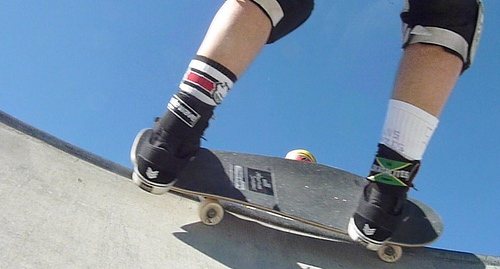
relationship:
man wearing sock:
[124, 0, 484, 247] [379, 98, 439, 163]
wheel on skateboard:
[186, 203, 248, 235] [179, 141, 447, 243]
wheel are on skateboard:
[375, 243, 401, 262] [229, 171, 356, 204]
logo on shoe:
[357, 221, 380, 243] [344, 165, 413, 255]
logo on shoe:
[138, 162, 160, 179] [134, 115, 192, 197]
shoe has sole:
[126, 125, 178, 195] [131, 127, 171, 194]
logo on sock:
[211, 80, 232, 102] [180, 53, 235, 112]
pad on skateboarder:
[394, 0, 485, 68] [130, 3, 487, 248]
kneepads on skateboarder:
[225, 0, 317, 45] [130, 3, 487, 248]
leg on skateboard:
[388, 10, 461, 217] [136, 138, 449, 255]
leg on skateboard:
[163, 3, 290, 144] [136, 138, 449, 255]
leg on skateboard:
[363, 0, 485, 207] [136, 138, 449, 255]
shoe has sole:
[341, 198, 446, 252] [131, 127, 179, 194]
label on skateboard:
[182, 160, 272, 197] [128, 130, 442, 267]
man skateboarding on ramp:
[124, 0, 484, 247] [1, 114, 494, 267]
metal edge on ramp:
[61, 133, 101, 178] [1, 114, 500, 269]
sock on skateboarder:
[166, 54, 236, 136] [130, 3, 487, 248]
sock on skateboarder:
[379, 98, 439, 163] [130, 3, 487, 248]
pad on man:
[400, 0, 484, 75] [124, 0, 484, 247]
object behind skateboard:
[284, 146, 316, 163] [166, 145, 444, 263]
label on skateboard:
[229, 160, 273, 195] [130, 120, 446, 262]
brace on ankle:
[351, 136, 421, 216] [333, 142, 427, 232]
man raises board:
[124, 0, 484, 247] [121, 115, 447, 267]